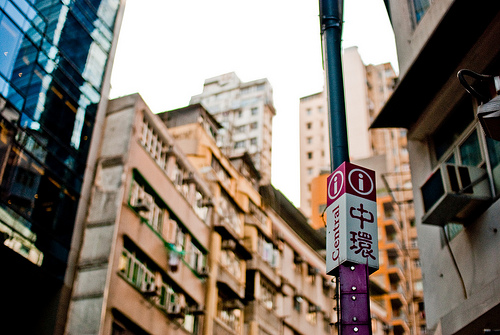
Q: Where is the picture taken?
A: City.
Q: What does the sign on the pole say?
A: Central.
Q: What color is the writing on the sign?
A: Purple.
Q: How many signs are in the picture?
A: One.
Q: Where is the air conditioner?
A: A window.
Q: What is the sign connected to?
A: A pole.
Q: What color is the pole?
A: Green.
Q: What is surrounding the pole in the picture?
A: Buildings.